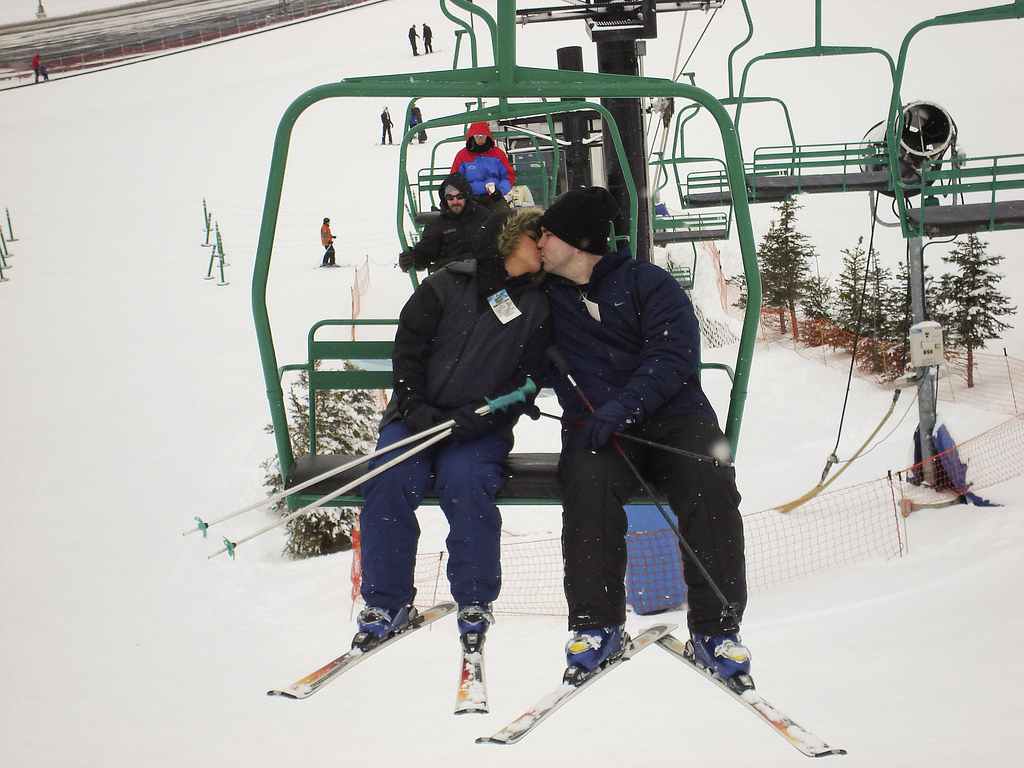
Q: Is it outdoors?
A: Yes, it is outdoors.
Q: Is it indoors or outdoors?
A: It is outdoors.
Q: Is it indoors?
A: No, it is outdoors.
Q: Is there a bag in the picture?
A: No, there are no bags.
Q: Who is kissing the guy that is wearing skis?
A: The girl is kissing the guy.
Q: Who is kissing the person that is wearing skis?
A: The girl is kissing the guy.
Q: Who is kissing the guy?
A: The girl is kissing the guy.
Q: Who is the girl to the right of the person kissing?
A: The girl is kissing the guy.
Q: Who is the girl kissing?
A: The girl is kissing the guy.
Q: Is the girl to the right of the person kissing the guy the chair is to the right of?
A: Yes, the girl is kissing the guy.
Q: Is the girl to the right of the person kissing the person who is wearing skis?
A: Yes, the girl is kissing the guy.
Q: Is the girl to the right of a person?
A: Yes, the girl is to the right of a person.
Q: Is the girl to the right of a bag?
A: No, the girl is to the right of a person.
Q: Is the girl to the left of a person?
A: No, the girl is to the right of a person.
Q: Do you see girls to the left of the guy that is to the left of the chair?
A: Yes, there is a girl to the left of the guy.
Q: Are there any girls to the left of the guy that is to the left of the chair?
A: Yes, there is a girl to the left of the guy.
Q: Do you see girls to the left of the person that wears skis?
A: Yes, there is a girl to the left of the guy.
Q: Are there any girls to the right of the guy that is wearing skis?
A: No, the girl is to the left of the guy.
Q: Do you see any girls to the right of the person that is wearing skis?
A: No, the girl is to the left of the guy.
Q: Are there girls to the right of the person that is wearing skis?
A: No, the girl is to the left of the guy.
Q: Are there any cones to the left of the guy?
A: No, there is a girl to the left of the guy.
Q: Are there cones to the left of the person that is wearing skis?
A: No, there is a girl to the left of the guy.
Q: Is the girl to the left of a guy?
A: Yes, the girl is to the left of a guy.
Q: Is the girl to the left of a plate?
A: No, the girl is to the left of a guy.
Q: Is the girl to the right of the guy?
A: No, the girl is to the left of the guy.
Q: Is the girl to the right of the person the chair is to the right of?
A: No, the girl is to the left of the guy.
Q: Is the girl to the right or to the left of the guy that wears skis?
A: The girl is to the left of the guy.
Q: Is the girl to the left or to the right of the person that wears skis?
A: The girl is to the left of the guy.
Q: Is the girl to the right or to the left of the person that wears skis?
A: The girl is to the left of the guy.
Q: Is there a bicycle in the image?
A: No, there are no bicycles.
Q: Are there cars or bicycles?
A: No, there are no bicycles or cars.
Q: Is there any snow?
A: Yes, there is snow.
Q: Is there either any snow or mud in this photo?
A: Yes, there is snow.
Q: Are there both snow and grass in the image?
A: No, there is snow but no grass.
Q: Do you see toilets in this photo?
A: No, there are no toilets.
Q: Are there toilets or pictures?
A: No, there are no toilets or pictures.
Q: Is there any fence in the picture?
A: Yes, there is a fence.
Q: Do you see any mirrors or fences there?
A: Yes, there is a fence.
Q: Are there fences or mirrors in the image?
A: Yes, there is a fence.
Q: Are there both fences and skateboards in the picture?
A: No, there is a fence but no skateboards.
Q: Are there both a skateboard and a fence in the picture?
A: No, there is a fence but no skateboards.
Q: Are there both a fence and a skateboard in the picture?
A: No, there is a fence but no skateboards.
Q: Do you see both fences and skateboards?
A: No, there is a fence but no skateboards.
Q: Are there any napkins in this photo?
A: No, there are no napkins.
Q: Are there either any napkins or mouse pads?
A: No, there are no napkins or mouse pads.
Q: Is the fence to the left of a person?
A: No, the fence is to the right of a person.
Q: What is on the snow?
A: The fence is on the snow.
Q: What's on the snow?
A: The fence is on the snow.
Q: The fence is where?
A: The fence is on the snow.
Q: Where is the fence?
A: The fence is on the snow.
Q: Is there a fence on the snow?
A: Yes, there is a fence on the snow.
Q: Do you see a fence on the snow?
A: Yes, there is a fence on the snow.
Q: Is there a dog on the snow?
A: No, there is a fence on the snow.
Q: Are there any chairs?
A: Yes, there is a chair.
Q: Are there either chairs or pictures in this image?
A: Yes, there is a chair.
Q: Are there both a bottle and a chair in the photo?
A: No, there is a chair but no bottles.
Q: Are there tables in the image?
A: No, there are no tables.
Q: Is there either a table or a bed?
A: No, there are no tables or beds.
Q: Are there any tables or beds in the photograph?
A: No, there are no tables or beds.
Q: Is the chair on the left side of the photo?
A: No, the chair is on the right of the image.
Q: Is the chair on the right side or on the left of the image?
A: The chair is on the right of the image.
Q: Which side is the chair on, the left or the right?
A: The chair is on the right of the image.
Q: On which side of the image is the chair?
A: The chair is on the right of the image.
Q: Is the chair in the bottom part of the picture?
A: No, the chair is in the top of the image.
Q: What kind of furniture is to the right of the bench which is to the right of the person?
A: The piece of furniture is a chair.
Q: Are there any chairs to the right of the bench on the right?
A: Yes, there is a chair to the right of the bench.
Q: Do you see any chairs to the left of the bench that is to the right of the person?
A: No, the chair is to the right of the bench.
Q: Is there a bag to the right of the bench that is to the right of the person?
A: No, there is a chair to the right of the bench.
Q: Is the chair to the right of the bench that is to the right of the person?
A: Yes, the chair is to the right of the bench.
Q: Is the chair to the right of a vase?
A: No, the chair is to the right of the bench.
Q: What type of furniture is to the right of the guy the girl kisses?
A: The piece of furniture is a chair.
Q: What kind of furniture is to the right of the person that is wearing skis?
A: The piece of furniture is a chair.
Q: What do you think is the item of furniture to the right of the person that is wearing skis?
A: The piece of furniture is a chair.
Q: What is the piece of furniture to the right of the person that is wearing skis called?
A: The piece of furniture is a chair.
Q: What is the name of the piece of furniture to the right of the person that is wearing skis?
A: The piece of furniture is a chair.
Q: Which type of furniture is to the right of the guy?
A: The piece of furniture is a chair.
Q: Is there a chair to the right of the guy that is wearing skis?
A: Yes, there is a chair to the right of the guy.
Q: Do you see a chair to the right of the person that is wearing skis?
A: Yes, there is a chair to the right of the guy.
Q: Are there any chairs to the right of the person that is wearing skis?
A: Yes, there is a chair to the right of the guy.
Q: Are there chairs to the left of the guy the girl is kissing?
A: No, the chair is to the right of the guy.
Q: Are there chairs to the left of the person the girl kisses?
A: No, the chair is to the right of the guy.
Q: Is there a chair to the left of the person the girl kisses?
A: No, the chair is to the right of the guy.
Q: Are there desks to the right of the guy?
A: No, there is a chair to the right of the guy.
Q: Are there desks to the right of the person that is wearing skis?
A: No, there is a chair to the right of the guy.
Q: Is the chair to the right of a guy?
A: Yes, the chair is to the right of a guy.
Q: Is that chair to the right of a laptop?
A: No, the chair is to the right of a guy.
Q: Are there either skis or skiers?
A: Yes, there are skis.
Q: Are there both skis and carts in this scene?
A: No, there are skis but no carts.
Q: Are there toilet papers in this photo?
A: No, there are no toilet papers.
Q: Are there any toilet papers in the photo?
A: No, there are no toilet papers.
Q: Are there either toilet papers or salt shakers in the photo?
A: No, there are no toilet papers or salt shakers.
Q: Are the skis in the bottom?
A: Yes, the skis are in the bottom of the image.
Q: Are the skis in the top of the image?
A: No, the skis are in the bottom of the image.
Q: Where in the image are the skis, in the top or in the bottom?
A: The skis are in the bottom of the image.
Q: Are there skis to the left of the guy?
A: Yes, there are skis to the left of the guy.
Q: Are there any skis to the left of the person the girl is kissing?
A: Yes, there are skis to the left of the guy.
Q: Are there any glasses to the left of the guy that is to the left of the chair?
A: No, there are skis to the left of the guy.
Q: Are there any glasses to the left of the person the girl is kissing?
A: No, there are skis to the left of the guy.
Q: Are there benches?
A: Yes, there is a bench.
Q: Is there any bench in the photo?
A: Yes, there is a bench.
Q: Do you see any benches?
A: Yes, there is a bench.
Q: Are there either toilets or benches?
A: Yes, there is a bench.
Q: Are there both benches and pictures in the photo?
A: No, there is a bench but no pictures.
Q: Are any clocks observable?
A: No, there are no clocks.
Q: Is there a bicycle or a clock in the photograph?
A: No, there are no clocks or bicycles.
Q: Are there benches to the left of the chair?
A: Yes, there is a bench to the left of the chair.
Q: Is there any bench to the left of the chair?
A: Yes, there is a bench to the left of the chair.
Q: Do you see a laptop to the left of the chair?
A: No, there is a bench to the left of the chair.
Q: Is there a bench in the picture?
A: Yes, there is a bench.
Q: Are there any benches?
A: Yes, there is a bench.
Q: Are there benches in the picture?
A: Yes, there is a bench.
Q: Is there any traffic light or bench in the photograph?
A: Yes, there is a bench.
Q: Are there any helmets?
A: No, there are no helmets.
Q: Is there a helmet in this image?
A: No, there are no helmets.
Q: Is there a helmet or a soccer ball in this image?
A: No, there are no helmets or soccer balls.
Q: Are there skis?
A: Yes, there are skis.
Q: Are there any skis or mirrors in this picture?
A: Yes, there are skis.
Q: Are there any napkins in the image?
A: No, there are no napkins.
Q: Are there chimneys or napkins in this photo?
A: No, there are no napkins or chimneys.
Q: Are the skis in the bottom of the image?
A: Yes, the skis are in the bottom of the image.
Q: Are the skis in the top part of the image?
A: No, the skis are in the bottom of the image.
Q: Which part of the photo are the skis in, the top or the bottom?
A: The skis are in the bottom of the image.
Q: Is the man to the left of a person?
A: No, the man is to the right of a person.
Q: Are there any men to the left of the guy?
A: Yes, there is a man to the left of the guy.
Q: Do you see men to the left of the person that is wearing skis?
A: Yes, there is a man to the left of the guy.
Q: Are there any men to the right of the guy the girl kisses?
A: No, the man is to the left of the guy.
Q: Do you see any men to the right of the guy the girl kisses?
A: No, the man is to the left of the guy.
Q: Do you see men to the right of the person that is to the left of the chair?
A: No, the man is to the left of the guy.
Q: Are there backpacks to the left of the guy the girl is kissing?
A: No, there is a man to the left of the guy.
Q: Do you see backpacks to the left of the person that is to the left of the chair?
A: No, there is a man to the left of the guy.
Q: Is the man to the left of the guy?
A: Yes, the man is to the left of the guy.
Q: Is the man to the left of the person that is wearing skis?
A: Yes, the man is to the left of the guy.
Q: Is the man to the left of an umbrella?
A: No, the man is to the left of the guy.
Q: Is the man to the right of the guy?
A: No, the man is to the left of the guy.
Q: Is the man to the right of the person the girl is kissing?
A: No, the man is to the left of the guy.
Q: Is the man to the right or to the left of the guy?
A: The man is to the left of the guy.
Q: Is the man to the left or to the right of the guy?
A: The man is to the left of the guy.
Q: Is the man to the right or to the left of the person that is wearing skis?
A: The man is to the left of the guy.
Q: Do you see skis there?
A: Yes, there are skis.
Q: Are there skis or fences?
A: Yes, there are skis.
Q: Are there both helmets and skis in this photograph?
A: No, there are skis but no helmets.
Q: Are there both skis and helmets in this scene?
A: No, there are skis but no helmets.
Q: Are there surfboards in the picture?
A: No, there are no surfboards.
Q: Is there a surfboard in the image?
A: No, there are no surfboards.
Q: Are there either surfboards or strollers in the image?
A: No, there are no surfboards or strollers.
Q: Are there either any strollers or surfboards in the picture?
A: No, there are no surfboards or strollers.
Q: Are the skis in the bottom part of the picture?
A: Yes, the skis are in the bottom of the image.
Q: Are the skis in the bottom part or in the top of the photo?
A: The skis are in the bottom of the image.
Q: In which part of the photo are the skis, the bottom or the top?
A: The skis are in the bottom of the image.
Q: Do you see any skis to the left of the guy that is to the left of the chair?
A: Yes, there are skis to the left of the guy.